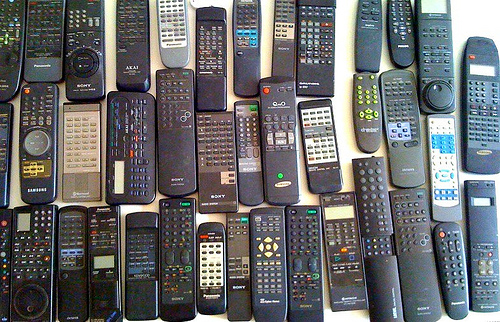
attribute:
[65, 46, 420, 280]
group — various shapes, different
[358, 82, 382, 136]
buttons — chartreuse, neon green, yellow, white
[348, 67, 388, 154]
remote — small, white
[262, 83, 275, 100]
button — red, rectangle, round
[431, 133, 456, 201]
areas — blue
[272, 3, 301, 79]
remote — narrow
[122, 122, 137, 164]
buttons — red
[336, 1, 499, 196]
table — white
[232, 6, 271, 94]
remote control — black, grey, blue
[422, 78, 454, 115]
dial — round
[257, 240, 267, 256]
arrow — yellow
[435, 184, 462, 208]
block — blue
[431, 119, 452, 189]
key pads — white, blue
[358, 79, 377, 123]
keys — green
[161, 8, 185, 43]
panel — gray, light blue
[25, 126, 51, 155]
button — large, gray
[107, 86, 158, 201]
remote control — landscape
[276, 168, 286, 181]
button — small, green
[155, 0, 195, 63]
remote — silver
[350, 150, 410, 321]
remote control — long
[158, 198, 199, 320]
remote control — black